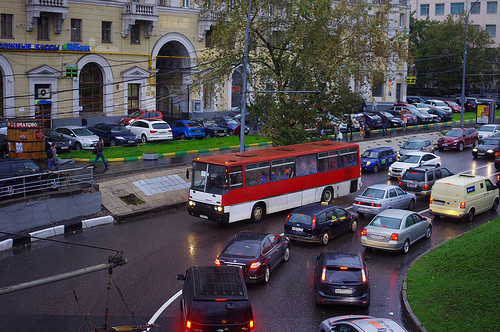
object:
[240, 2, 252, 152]
street post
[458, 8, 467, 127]
street post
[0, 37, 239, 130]
wire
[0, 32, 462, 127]
wire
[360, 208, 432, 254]
car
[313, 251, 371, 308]
car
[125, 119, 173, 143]
car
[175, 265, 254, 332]
car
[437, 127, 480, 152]
car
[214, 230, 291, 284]
car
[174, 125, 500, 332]
cars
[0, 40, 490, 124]
wires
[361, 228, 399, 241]
tail lights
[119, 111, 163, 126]
car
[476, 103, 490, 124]
sign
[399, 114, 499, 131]
sidewalk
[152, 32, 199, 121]
arch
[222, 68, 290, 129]
wall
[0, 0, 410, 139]
building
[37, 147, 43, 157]
wood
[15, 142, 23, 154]
sign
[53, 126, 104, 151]
car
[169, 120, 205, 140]
car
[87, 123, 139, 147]
car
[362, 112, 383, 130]
car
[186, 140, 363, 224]
bus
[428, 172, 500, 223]
car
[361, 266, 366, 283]
light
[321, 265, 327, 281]
light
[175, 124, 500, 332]
traffic jam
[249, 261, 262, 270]
light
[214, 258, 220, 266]
light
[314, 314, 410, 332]
car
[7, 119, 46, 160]
sign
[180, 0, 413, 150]
tree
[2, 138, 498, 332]
road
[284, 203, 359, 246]
car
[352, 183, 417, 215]
car